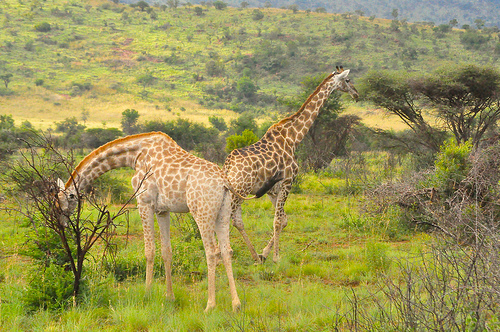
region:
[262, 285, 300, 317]
this is the grass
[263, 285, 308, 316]
the grass is green in color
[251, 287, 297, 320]
the grass is tall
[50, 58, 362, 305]
these are two giraffes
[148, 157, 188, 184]
the fur is brown in color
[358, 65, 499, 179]
these are some trees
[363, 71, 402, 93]
the leaves are green in color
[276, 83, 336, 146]
the neck is long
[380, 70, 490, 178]
the tree is tall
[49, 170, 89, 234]
the giraffe is feeding on twigs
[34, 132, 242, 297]
giraffe eating out of tree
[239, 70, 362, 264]
giraffe eating out of tree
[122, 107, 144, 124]
bright green tree on hill side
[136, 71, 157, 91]
bright green tree on hill side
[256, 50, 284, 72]
bright green tree on hill side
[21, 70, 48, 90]
bright green tree on hill side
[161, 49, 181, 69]
bright green tree on hill side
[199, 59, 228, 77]
bright green tree on hill side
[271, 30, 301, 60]
bright green tree on hill side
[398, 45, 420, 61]
bright green tree on hill side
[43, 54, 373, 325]
giraffes in the plains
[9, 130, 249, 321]
giraffe grazing on leaves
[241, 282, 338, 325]
green grass on the ground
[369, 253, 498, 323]
bare tree in the grass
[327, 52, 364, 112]
head of a giraffe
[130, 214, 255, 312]
legs of a giraffe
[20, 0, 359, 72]
grassy hill in a plain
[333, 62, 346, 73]
horns on a giraffe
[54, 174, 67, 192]
right ear of a giraffe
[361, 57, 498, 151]
green trees on a plain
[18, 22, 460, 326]
Two giraffes in a green grassy area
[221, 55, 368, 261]
A giraffe with brown spots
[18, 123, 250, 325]
A giraffe that is eating leaves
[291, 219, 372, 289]
An area of green grass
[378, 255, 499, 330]
Brown tree limbs with no leaves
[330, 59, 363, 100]
A giraffe's head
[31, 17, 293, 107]
A green hill in the background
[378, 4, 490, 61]
Trees growing on a green hill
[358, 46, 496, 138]
A green tree in the background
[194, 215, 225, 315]
A giraffe's leg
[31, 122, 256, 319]
giraffe is feeding on a bare bush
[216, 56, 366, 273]
giraffe is facing the hills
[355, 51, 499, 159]
large bush tree in middle of field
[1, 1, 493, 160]
hillside with scarce bushes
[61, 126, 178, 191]
light colored mane on giraffe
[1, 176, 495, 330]
grass amongs field is green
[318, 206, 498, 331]
bare limbs on bush behind giraffe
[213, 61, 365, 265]
tall giraffe is brown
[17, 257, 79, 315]
small bush under bare limbs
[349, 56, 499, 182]
large bush is dark green